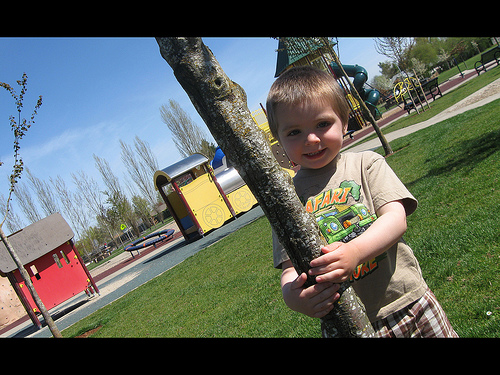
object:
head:
[265, 66, 349, 169]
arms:
[304, 180, 378, 283]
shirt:
[270, 149, 430, 324]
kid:
[265, 65, 458, 338]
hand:
[280, 271, 340, 318]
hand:
[307, 241, 361, 283]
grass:
[442, 273, 495, 311]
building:
[0, 211, 88, 335]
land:
[2, 35, 498, 336]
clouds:
[41, 113, 97, 148]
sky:
[4, 38, 106, 63]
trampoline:
[124, 229, 175, 260]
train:
[122, 229, 174, 252]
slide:
[329, 61, 381, 122]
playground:
[243, 35, 500, 152]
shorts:
[320, 287, 460, 338]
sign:
[120, 223, 129, 233]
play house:
[0, 209, 98, 332]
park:
[97, 35, 499, 338]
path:
[384, 75, 500, 142]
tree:
[155, 37, 375, 335]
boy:
[264, 65, 457, 337]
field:
[46, 97, 500, 339]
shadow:
[399, 129, 500, 186]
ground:
[0, 42, 500, 338]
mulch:
[68, 318, 109, 338]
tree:
[0, 70, 63, 338]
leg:
[129, 251, 135, 259]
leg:
[136, 250, 140, 255]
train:
[152, 149, 297, 239]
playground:
[0, 147, 261, 337]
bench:
[474, 47, 495, 76]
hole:
[214, 78, 221, 87]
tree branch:
[0, 72, 43, 226]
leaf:
[19, 159, 23, 161]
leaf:
[18, 176, 21, 178]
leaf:
[11, 188, 15, 192]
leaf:
[24, 88, 27, 91]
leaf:
[10, 116, 14, 118]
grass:
[177, 302, 218, 331]